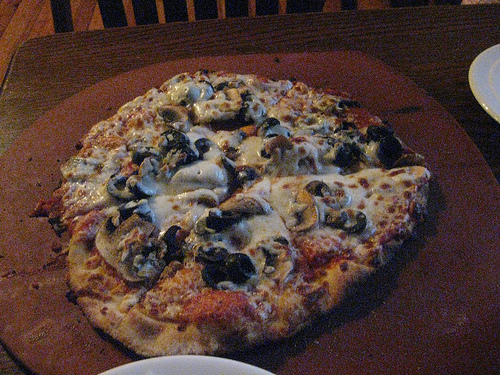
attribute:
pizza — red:
[58, 67, 432, 357]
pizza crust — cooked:
[223, 281, 374, 343]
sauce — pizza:
[33, 183, 64, 232]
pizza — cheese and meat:
[42, 37, 470, 342]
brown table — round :
[97, 5, 499, 61]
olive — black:
[320, 133, 379, 176]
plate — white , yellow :
[450, 43, 497, 134]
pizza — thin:
[45, 263, 180, 342]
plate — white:
[463, 37, 498, 139]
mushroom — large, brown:
[89, 207, 168, 288]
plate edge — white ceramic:
[468, 38, 498, 125]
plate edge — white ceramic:
[99, 356, 274, 373]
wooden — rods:
[55, 2, 291, 17]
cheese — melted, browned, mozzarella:
[251, 160, 314, 205]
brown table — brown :
[7, 14, 486, 61]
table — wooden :
[0, 5, 500, 374]